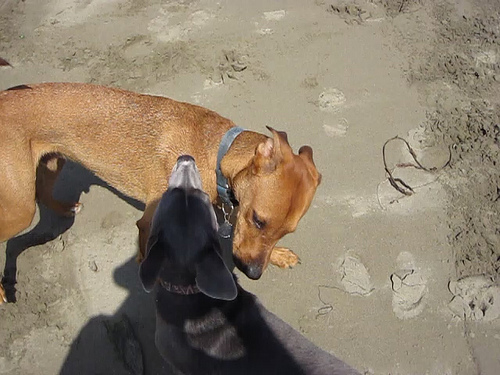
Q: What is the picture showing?
A: It is showing a beach.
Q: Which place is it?
A: It is a beach.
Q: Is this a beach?
A: Yes, it is a beach.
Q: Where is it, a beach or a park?
A: It is a beach.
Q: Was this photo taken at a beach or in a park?
A: It was taken at a beach.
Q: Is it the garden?
A: No, it is the beach.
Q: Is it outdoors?
A: Yes, it is outdoors.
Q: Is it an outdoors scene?
A: Yes, it is outdoors.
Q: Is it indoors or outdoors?
A: It is outdoors.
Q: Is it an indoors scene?
A: No, it is outdoors.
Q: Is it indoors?
A: No, it is outdoors.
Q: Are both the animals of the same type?
A: Yes, all the animals are dogs.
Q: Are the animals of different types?
A: No, all the animals are dogs.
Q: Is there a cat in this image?
A: No, there are no cats.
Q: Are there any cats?
A: No, there are no cats.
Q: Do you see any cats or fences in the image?
A: No, there are no cats or fences.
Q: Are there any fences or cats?
A: No, there are no cats or fences.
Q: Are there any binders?
A: No, there are no binders.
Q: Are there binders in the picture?
A: No, there are no binders.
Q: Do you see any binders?
A: No, there are no binders.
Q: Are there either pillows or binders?
A: No, there are no binders or pillows.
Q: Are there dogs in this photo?
A: Yes, there is a dog.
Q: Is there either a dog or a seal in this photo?
A: Yes, there is a dog.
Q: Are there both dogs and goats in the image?
A: No, there is a dog but no goats.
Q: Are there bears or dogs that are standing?
A: Yes, the dog is standing.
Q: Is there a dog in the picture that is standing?
A: Yes, there is a dog that is standing.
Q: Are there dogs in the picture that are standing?
A: Yes, there is a dog that is standing.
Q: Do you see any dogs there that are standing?
A: Yes, there is a dog that is standing.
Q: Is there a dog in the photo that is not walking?
A: Yes, there is a dog that is standing.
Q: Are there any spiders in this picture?
A: No, there are no spiders.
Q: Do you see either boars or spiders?
A: No, there are no spiders or boars.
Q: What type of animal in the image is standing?
A: The animal is a dog.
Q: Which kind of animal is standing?
A: The animal is a dog.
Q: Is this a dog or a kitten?
A: This is a dog.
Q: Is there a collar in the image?
A: Yes, there is a collar.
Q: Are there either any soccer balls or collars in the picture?
A: Yes, there is a collar.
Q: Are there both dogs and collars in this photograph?
A: Yes, there are both a collar and a dog.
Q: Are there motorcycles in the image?
A: No, there are no motorcycles.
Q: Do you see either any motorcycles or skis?
A: No, there are no motorcycles or skis.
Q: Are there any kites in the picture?
A: No, there are no kites.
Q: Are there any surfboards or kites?
A: No, there are no kites or surfboards.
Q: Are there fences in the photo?
A: No, there are no fences.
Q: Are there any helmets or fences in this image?
A: No, there are no fences or helmets.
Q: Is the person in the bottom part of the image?
A: Yes, the person is in the bottom of the image.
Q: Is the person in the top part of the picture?
A: No, the person is in the bottom of the image.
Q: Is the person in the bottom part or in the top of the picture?
A: The person is in the bottom of the image.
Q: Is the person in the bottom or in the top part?
A: The person is in the bottom of the image.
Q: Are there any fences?
A: No, there are no fences.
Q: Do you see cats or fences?
A: No, there are no fences or cats.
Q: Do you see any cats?
A: No, there are no cats.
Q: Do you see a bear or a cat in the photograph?
A: No, there are no cats or bears.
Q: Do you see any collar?
A: Yes, there is a collar.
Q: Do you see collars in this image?
A: Yes, there is a collar.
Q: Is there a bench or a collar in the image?
A: Yes, there is a collar.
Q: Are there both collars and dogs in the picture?
A: Yes, there are both a collar and a dog.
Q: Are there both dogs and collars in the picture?
A: Yes, there are both a collar and a dog.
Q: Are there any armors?
A: No, there are no armors.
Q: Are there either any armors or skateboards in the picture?
A: No, there are no armors or skateboards.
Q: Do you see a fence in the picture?
A: No, there are no fences.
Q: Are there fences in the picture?
A: No, there are no fences.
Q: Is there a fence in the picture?
A: No, there are no fences.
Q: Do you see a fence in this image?
A: No, there are no fences.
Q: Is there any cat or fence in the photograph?
A: No, there are no fences or cats.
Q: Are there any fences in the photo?
A: No, there are no fences.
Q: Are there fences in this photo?
A: No, there are no fences.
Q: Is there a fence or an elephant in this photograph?
A: No, there are no fences or elephants.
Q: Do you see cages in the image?
A: No, there are no cages.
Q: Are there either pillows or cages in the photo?
A: No, there are no cages or pillows.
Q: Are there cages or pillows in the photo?
A: No, there are no cages or pillows.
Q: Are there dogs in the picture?
A: Yes, there is a dog.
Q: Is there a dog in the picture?
A: Yes, there is a dog.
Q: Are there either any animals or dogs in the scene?
A: Yes, there is a dog.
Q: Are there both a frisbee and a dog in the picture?
A: No, there is a dog but no frisbees.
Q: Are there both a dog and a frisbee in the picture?
A: No, there is a dog but no frisbees.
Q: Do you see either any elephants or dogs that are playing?
A: Yes, the dog is playing.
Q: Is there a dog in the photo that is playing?
A: Yes, there is a dog that is playing.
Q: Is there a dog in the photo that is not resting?
A: Yes, there is a dog that is playing.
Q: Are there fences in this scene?
A: No, there are no fences.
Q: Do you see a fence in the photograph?
A: No, there are no fences.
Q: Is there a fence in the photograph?
A: No, there are no fences.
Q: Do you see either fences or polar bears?
A: No, there are no fences or polar bears.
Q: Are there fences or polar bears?
A: No, there are no fences or polar bears.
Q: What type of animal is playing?
A: The animal is a dog.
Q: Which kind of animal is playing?
A: The animal is a dog.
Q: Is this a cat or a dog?
A: This is a dog.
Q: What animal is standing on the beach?
A: The dog is standing on the beach.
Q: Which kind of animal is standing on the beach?
A: The animal is a dog.